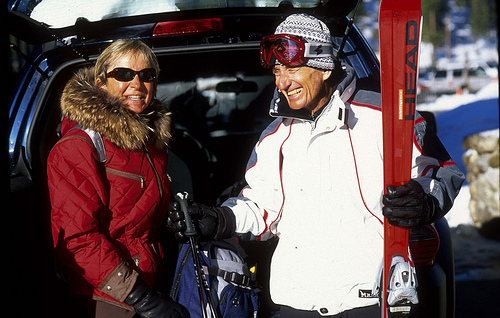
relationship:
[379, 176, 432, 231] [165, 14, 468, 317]
hand of man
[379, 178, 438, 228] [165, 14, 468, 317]
hand of man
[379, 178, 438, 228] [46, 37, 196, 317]
hand of person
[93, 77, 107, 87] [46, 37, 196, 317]
ear of person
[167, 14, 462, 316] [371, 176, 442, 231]
man wearing gloves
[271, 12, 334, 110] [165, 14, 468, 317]
head of man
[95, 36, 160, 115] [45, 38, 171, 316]
head of person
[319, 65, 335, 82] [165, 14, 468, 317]
ear of man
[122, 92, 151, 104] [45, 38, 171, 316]
smile of person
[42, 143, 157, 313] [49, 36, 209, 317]
arm of person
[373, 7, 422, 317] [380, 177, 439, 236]
skis in hand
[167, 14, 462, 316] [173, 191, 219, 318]
man holding ski pole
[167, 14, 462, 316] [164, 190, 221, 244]
man wearing glove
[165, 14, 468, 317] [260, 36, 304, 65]
man wearing goggles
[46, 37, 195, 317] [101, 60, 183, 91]
person wearing sunglasses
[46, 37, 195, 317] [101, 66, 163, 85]
person wearing sun glasses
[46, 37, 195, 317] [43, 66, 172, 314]
person wearing winter jacket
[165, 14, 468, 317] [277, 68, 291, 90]
man has nose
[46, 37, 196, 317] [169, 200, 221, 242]
person has hand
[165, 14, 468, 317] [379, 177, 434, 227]
man has hand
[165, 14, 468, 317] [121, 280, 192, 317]
man has hand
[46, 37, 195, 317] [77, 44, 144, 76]
person has hair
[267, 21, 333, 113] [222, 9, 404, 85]
head has knit hat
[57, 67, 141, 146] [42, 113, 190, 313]
brown fur on jacket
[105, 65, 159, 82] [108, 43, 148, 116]
sunglasses are on face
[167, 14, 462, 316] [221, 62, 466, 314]
man wearing jacket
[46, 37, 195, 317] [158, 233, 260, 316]
person holding blue backpack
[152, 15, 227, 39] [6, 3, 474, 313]
break light at top of car